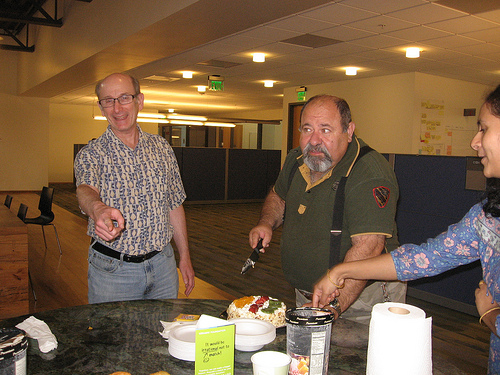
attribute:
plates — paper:
[162, 317, 234, 364]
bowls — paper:
[364, 301, 433, 373]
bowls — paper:
[229, 316, 276, 351]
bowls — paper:
[167, 322, 203, 359]